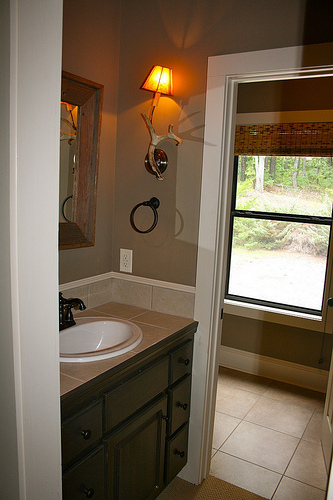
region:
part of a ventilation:
[254, 254, 309, 301]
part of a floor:
[230, 430, 259, 462]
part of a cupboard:
[115, 433, 164, 480]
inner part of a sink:
[89, 328, 124, 339]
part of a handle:
[179, 399, 192, 413]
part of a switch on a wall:
[118, 248, 133, 267]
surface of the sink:
[146, 315, 171, 328]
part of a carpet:
[207, 481, 222, 495]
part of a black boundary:
[282, 213, 315, 225]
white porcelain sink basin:
[53, 317, 145, 364]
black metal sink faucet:
[56, 289, 88, 334]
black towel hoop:
[125, 192, 173, 242]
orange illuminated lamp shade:
[138, 59, 180, 115]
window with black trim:
[223, 115, 331, 328]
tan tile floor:
[218, 380, 319, 485]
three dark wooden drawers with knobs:
[164, 336, 202, 481]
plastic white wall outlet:
[116, 244, 137, 277]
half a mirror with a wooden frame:
[57, 61, 113, 255]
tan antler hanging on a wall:
[136, 107, 191, 184]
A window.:
[234, 153, 325, 318]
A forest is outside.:
[229, 152, 324, 277]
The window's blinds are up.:
[229, 115, 326, 154]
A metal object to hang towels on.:
[112, 184, 168, 242]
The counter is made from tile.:
[51, 293, 184, 397]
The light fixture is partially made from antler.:
[130, 57, 186, 181]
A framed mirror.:
[52, 69, 109, 253]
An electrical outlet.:
[106, 241, 140, 284]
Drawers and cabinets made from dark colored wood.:
[66, 333, 194, 495]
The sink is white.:
[53, 305, 138, 372]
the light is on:
[137, 57, 184, 109]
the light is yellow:
[136, 64, 194, 111]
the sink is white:
[60, 314, 162, 363]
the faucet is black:
[57, 292, 96, 334]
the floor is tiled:
[228, 399, 305, 495]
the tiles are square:
[216, 413, 309, 484]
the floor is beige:
[228, 403, 310, 495]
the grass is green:
[254, 225, 282, 247]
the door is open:
[204, 44, 331, 495]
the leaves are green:
[273, 164, 319, 196]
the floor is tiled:
[236, 378, 290, 470]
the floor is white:
[236, 390, 296, 497]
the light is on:
[126, 43, 195, 116]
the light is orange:
[128, 43, 187, 119]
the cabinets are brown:
[80, 375, 225, 485]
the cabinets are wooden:
[97, 364, 208, 493]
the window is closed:
[228, 134, 323, 338]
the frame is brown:
[77, 66, 106, 252]